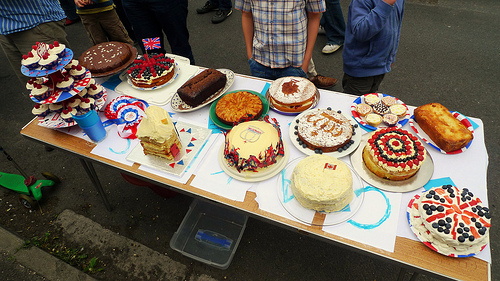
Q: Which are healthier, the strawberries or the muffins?
A: The strawberries are healthier than the muffins.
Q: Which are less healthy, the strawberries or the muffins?
A: The muffins are less healthy than the strawberries.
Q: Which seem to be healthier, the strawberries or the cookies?
A: The strawberries are healthier than the cookies.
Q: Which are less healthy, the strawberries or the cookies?
A: The cookies are less healthy than the strawberries.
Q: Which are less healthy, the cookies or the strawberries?
A: The cookies are less healthy than the strawberries.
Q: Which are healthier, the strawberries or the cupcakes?
A: The strawberries are healthier than the cupcakes.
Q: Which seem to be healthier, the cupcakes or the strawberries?
A: The strawberries are healthier than the cupcakes.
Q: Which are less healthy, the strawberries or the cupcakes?
A: The cupcakes are less healthy than the strawberries.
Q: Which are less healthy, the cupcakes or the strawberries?
A: The cupcakes are less healthy than the strawberries.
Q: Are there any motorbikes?
A: No, there are no motorbikes.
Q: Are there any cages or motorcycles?
A: No, there are no motorcycles or cages.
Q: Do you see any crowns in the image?
A: Yes, there is a crown.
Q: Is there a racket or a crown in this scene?
A: Yes, there is a crown.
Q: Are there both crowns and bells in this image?
A: No, there is a crown but no bells.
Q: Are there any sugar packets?
A: No, there are no sugar packets.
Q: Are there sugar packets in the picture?
A: No, there are no sugar packets.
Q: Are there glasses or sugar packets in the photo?
A: No, there are no sugar packets or glasses.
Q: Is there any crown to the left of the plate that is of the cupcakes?
A: Yes, there is a crown to the left of the plate.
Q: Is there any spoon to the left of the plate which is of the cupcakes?
A: No, there is a crown to the left of the plate.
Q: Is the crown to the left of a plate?
A: Yes, the crown is to the left of a plate.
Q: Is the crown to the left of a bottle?
A: No, the crown is to the left of a plate.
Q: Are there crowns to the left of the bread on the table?
A: Yes, there is a crown to the left of the bread.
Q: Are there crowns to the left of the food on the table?
A: Yes, there is a crown to the left of the bread.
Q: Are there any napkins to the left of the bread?
A: No, there is a crown to the left of the bread.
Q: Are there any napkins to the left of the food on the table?
A: No, there is a crown to the left of the bread.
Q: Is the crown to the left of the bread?
A: Yes, the crown is to the left of the bread.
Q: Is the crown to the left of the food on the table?
A: Yes, the crown is to the left of the bread.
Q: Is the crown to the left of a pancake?
A: No, the crown is to the left of the bread.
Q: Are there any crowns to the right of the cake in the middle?
A: Yes, there is a crown to the right of the cake.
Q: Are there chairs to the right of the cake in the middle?
A: No, there is a crown to the right of the cake.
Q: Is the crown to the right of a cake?
A: Yes, the crown is to the right of a cake.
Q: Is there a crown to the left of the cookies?
A: Yes, there is a crown to the left of the cookies.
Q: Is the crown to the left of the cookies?
A: Yes, the crown is to the left of the cookies.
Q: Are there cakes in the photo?
A: Yes, there is a cake.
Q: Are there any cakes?
A: Yes, there is a cake.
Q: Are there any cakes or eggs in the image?
A: Yes, there is a cake.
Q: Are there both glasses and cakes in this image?
A: No, there is a cake but no glasses.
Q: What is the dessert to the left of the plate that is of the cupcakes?
A: The dessert is a cake.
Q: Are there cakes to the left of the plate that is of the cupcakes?
A: Yes, there is a cake to the left of the plate.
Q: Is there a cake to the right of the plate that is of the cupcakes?
A: No, the cake is to the left of the plate.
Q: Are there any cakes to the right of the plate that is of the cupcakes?
A: No, the cake is to the left of the plate.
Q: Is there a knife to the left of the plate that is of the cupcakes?
A: No, there is a cake to the left of the plate.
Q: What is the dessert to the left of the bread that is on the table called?
A: The dessert is a cake.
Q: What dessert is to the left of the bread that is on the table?
A: The dessert is a cake.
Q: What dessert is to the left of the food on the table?
A: The dessert is a cake.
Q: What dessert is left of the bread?
A: The dessert is a cake.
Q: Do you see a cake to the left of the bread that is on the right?
A: Yes, there is a cake to the left of the bread.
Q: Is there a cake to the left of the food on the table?
A: Yes, there is a cake to the left of the bread.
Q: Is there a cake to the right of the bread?
A: No, the cake is to the left of the bread.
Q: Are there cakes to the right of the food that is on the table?
A: No, the cake is to the left of the bread.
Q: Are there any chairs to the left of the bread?
A: No, there is a cake to the left of the bread.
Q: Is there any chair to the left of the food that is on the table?
A: No, there is a cake to the left of the bread.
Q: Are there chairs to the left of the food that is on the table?
A: No, there is a cake to the left of the bread.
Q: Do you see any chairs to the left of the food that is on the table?
A: No, there is a cake to the left of the bread.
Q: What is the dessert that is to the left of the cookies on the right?
A: The dessert is a cake.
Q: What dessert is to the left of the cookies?
A: The dessert is a cake.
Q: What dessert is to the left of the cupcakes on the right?
A: The dessert is a cake.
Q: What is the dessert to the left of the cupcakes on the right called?
A: The dessert is a cake.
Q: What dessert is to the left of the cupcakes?
A: The dessert is a cake.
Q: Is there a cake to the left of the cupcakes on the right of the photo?
A: Yes, there is a cake to the left of the cupcakes.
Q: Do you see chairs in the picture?
A: No, there are no chairs.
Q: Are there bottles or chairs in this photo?
A: No, there are no chairs or bottles.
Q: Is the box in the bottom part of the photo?
A: Yes, the box is in the bottom of the image.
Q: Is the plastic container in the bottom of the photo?
A: Yes, the box is in the bottom of the image.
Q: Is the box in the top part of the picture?
A: No, the box is in the bottom of the image.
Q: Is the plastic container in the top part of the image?
A: No, the box is in the bottom of the image.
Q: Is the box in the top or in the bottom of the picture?
A: The box is in the bottom of the image.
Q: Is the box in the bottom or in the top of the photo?
A: The box is in the bottom of the image.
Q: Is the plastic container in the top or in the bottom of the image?
A: The box is in the bottom of the image.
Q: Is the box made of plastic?
A: Yes, the box is made of plastic.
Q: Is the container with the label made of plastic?
A: Yes, the box is made of plastic.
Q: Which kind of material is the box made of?
A: The box is made of plastic.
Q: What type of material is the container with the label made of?
A: The box is made of plastic.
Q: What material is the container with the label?
A: The box is made of plastic.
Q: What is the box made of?
A: The box is made of plastic.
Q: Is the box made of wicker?
A: No, the box is made of plastic.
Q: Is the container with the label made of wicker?
A: No, the box is made of plastic.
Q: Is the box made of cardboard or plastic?
A: The box is made of plastic.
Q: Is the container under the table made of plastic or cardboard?
A: The box is made of plastic.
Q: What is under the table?
A: The box is under the table.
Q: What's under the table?
A: The box is under the table.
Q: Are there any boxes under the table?
A: Yes, there is a box under the table.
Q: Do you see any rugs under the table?
A: No, there is a box under the table.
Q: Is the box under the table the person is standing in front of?
A: Yes, the box is under the table.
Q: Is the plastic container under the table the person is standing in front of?
A: Yes, the box is under the table.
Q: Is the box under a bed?
A: No, the box is under the table.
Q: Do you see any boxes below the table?
A: Yes, there is a box below the table.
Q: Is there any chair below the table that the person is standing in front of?
A: No, there is a box below the table.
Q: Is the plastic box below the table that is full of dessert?
A: Yes, the box is below the table.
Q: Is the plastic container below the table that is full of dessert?
A: Yes, the box is below the table.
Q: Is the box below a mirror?
A: No, the box is below the table.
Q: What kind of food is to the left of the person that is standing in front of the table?
A: The food is a dessert.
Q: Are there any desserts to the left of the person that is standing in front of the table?
A: Yes, there is a dessert to the left of the person.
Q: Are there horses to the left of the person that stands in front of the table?
A: No, there is a dessert to the left of the person.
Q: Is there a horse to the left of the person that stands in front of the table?
A: No, there is a dessert to the left of the person.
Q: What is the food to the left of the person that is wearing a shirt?
A: The food is a dessert.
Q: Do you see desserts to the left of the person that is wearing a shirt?
A: Yes, there is a dessert to the left of the person.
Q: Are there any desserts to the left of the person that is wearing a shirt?
A: Yes, there is a dessert to the left of the person.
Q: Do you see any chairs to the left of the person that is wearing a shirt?
A: No, there is a dessert to the left of the person.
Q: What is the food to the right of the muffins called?
A: The food is a dessert.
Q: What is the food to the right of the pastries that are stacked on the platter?
A: The food is a dessert.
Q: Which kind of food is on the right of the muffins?
A: The food is a dessert.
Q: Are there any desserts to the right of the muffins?
A: Yes, there is a dessert to the right of the muffins.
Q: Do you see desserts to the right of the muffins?
A: Yes, there is a dessert to the right of the muffins.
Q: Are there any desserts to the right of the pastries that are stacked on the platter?
A: Yes, there is a dessert to the right of the muffins.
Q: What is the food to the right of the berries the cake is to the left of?
A: The food is a dessert.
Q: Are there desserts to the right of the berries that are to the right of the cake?
A: Yes, there is a dessert to the right of the berries.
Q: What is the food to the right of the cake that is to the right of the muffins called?
A: The food is a dessert.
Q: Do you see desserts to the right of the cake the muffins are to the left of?
A: Yes, there is a dessert to the right of the cake.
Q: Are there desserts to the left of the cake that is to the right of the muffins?
A: No, the dessert is to the right of the cake.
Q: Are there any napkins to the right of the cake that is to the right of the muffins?
A: No, there is a dessert to the right of the cake.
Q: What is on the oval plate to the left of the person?
A: The dessert is on the plate.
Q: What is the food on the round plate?
A: The food is a dessert.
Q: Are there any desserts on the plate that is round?
A: Yes, there is a dessert on the plate.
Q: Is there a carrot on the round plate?
A: No, there is a dessert on the plate.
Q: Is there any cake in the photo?
A: Yes, there is a cake.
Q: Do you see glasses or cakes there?
A: Yes, there is a cake.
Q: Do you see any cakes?
A: Yes, there is a cake.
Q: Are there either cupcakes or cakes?
A: Yes, there is a cake.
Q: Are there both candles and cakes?
A: No, there is a cake but no candles.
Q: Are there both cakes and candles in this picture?
A: No, there is a cake but no candles.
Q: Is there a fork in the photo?
A: No, there are no forks.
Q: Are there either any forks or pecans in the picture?
A: No, there are no forks or pecans.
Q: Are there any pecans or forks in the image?
A: No, there are no forks or pecans.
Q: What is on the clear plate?
A: The cake is on the plate.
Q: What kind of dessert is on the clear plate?
A: The dessert is a cake.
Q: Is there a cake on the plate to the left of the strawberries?
A: Yes, there is a cake on the plate.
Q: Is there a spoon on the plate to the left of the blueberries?
A: No, there is a cake on the plate.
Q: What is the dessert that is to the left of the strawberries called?
A: The dessert is a cake.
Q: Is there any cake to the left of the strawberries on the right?
A: Yes, there is a cake to the left of the strawberries.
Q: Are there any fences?
A: No, there are no fences.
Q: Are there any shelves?
A: No, there are no shelves.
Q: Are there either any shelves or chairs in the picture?
A: No, there are no shelves or chairs.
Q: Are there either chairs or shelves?
A: No, there are no shelves or chairs.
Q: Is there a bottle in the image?
A: No, there are no bottles.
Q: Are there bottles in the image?
A: No, there are no bottles.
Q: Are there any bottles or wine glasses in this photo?
A: No, there are no bottles or wine glasses.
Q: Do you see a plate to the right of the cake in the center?
A: Yes, there are plates to the right of the cake.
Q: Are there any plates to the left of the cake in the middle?
A: No, the plates are to the right of the cake.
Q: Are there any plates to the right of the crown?
A: Yes, there are plates to the right of the crown.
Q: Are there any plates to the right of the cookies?
A: Yes, there are plates to the right of the cookies.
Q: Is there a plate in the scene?
A: Yes, there is a plate.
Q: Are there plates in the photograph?
A: Yes, there is a plate.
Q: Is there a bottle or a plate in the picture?
A: Yes, there is a plate.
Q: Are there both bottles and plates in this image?
A: No, there is a plate but no bottles.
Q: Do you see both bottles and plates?
A: No, there is a plate but no bottles.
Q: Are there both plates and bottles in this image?
A: No, there is a plate but no bottles.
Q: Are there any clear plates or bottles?
A: Yes, there is a clear plate.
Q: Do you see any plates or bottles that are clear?
A: Yes, the plate is clear.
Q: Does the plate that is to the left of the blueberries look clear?
A: Yes, the plate is clear.